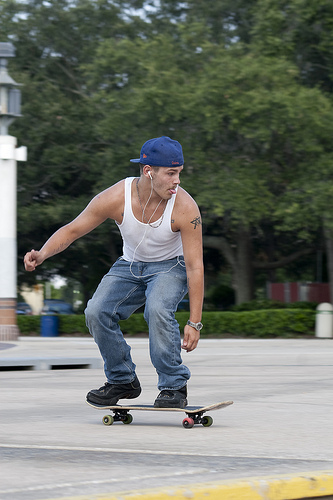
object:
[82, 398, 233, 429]
board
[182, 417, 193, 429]
wheel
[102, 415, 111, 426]
wheel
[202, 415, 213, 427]
wheel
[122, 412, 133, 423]
wheel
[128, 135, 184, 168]
cap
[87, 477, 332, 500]
yellow paint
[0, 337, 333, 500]
sidewalk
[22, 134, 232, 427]
skate boarding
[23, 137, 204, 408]
boy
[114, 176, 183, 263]
shirt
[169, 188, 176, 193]
tongue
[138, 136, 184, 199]
head